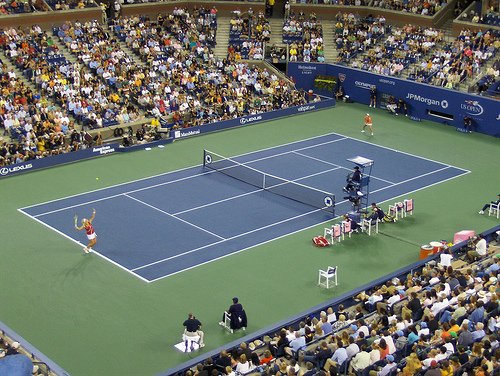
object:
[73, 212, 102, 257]
player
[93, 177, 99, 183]
ball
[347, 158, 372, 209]
referee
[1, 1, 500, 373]
stadium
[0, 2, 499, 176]
audience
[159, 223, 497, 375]
audience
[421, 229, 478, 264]
coolers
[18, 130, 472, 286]
court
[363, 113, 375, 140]
player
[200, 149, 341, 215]
net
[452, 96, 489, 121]
sponsors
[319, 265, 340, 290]
chair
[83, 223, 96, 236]
red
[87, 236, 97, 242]
white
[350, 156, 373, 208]
chair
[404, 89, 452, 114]
ad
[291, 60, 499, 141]
wall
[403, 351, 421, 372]
person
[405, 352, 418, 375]
yellow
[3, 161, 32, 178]
ad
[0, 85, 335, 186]
wall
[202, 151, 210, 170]
pole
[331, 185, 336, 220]
pole